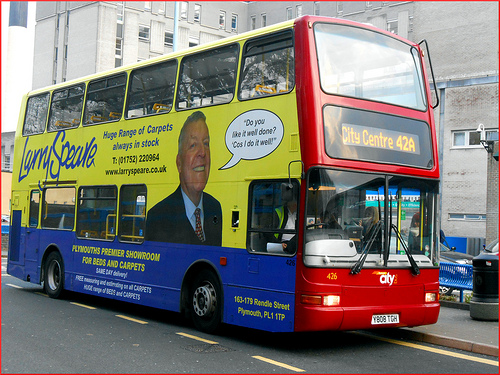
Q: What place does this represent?
A: It represents the road.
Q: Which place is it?
A: It is a road.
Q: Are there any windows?
A: Yes, there is a window.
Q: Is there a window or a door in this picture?
A: Yes, there is a window.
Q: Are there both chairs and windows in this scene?
A: No, there is a window but no chairs.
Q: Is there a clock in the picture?
A: No, there are no clocks.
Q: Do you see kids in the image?
A: No, there are no kids.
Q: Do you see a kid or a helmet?
A: No, there are no children or helmets.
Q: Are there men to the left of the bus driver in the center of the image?
A: Yes, there is a man to the left of the bus driver.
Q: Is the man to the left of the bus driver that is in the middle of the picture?
A: Yes, the man is to the left of the bus driver.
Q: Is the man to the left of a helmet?
A: No, the man is to the left of the bus driver.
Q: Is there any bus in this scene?
A: Yes, there is a bus.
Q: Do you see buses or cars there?
A: Yes, there is a bus.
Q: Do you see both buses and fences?
A: No, there is a bus but no fences.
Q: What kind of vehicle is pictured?
A: The vehicle is a bus.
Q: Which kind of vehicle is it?
A: The vehicle is a bus.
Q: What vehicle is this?
A: This is a bus.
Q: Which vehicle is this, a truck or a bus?
A: This is a bus.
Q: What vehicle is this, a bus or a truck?
A: This is a bus.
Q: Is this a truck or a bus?
A: This is a bus.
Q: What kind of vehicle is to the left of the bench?
A: The vehicle is a bus.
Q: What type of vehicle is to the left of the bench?
A: The vehicle is a bus.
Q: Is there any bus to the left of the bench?
A: Yes, there is a bus to the left of the bench.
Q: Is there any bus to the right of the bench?
A: No, the bus is to the left of the bench.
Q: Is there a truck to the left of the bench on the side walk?
A: No, there is a bus to the left of the bench.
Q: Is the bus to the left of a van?
A: No, the bus is to the left of a bench.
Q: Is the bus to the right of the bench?
A: No, the bus is to the left of the bench.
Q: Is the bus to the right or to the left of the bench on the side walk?
A: The bus is to the left of the bench.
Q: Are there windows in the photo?
A: Yes, there is a window.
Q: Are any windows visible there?
A: Yes, there is a window.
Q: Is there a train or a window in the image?
A: Yes, there is a window.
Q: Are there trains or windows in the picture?
A: Yes, there is a window.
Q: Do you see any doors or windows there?
A: Yes, there is a window.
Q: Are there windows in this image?
A: Yes, there is a window.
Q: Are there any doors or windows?
A: Yes, there is a window.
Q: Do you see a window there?
A: Yes, there are windows.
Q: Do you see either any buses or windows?
A: Yes, there are windows.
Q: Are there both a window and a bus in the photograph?
A: Yes, there are both a window and a bus.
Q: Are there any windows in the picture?
A: Yes, there is a window.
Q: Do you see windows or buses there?
A: Yes, there is a window.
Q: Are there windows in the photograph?
A: Yes, there is a window.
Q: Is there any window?
A: Yes, there is a window.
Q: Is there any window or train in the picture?
A: Yes, there is a window.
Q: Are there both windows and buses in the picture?
A: Yes, there are both a window and a bus.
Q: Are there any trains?
A: No, there are no trains.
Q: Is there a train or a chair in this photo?
A: No, there are no trains or chairs.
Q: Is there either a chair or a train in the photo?
A: No, there are no trains or chairs.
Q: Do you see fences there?
A: No, there are no fences.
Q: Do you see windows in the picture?
A: Yes, there is a window.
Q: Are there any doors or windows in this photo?
A: Yes, there is a window.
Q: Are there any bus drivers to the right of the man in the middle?
A: Yes, there is a bus driver to the right of the man.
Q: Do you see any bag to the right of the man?
A: No, there is a bus driver to the right of the man.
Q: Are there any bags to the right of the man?
A: No, there is a bus driver to the right of the man.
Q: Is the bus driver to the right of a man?
A: Yes, the bus driver is to the right of a man.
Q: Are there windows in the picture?
A: Yes, there is a window.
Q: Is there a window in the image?
A: Yes, there is a window.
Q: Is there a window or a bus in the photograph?
A: Yes, there is a window.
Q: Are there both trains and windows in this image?
A: No, there is a window but no trains.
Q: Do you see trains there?
A: No, there are no trains.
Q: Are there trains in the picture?
A: No, there are no trains.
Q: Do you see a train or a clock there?
A: No, there are no trains or clocks.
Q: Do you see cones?
A: No, there are no cones.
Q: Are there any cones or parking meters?
A: No, there are no cones or parking meters.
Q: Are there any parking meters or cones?
A: No, there are no cones or parking meters.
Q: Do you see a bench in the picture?
A: Yes, there is a bench.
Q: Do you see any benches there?
A: Yes, there is a bench.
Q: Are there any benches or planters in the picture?
A: Yes, there is a bench.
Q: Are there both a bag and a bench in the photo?
A: No, there is a bench but no bags.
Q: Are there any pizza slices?
A: No, there are no pizza slices.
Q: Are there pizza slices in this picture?
A: No, there are no pizza slices.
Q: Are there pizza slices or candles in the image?
A: No, there are no pizza slices or candles.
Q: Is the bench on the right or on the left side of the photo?
A: The bench is on the right of the image.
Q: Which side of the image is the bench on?
A: The bench is on the right of the image.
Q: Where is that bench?
A: The bench is on the sidewalk.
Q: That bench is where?
A: The bench is on the sidewalk.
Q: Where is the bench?
A: The bench is on the sidewalk.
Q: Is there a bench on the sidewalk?
A: Yes, there is a bench on the sidewalk.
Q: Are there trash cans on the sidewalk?
A: No, there is a bench on the sidewalk.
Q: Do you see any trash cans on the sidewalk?
A: No, there is a bench on the sidewalk.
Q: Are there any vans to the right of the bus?
A: No, there is a bench to the right of the bus.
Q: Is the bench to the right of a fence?
A: No, the bench is to the right of the bus.